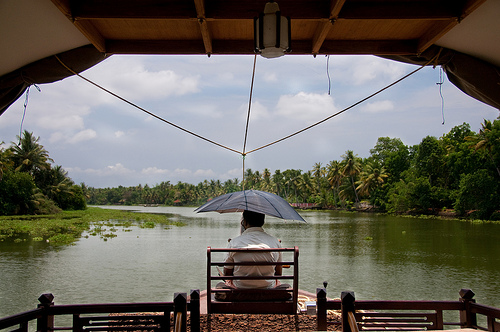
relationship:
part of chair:
[216, 247, 286, 252] [208, 241, 298, 313]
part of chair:
[251, 286, 279, 298] [198, 241, 325, 312]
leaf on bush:
[410, 184, 413, 189] [388, 168, 447, 217]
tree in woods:
[449, 172, 477, 216] [17, 109, 488, 242]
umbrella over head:
[210, 179, 315, 230] [223, 204, 284, 233]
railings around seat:
[42, 293, 197, 322] [208, 253, 298, 312]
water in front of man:
[56, 193, 177, 293] [220, 213, 295, 310]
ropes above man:
[201, 108, 331, 151] [200, 209, 272, 279]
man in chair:
[224, 218, 284, 267] [178, 236, 328, 330]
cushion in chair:
[214, 287, 292, 305] [209, 250, 303, 282]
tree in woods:
[449, 172, 477, 216] [345, 151, 483, 225]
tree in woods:
[399, 169, 466, 207] [367, 157, 453, 208]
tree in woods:
[449, 172, 477, 216] [411, 163, 464, 207]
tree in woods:
[340, 166, 397, 215] [337, 167, 381, 198]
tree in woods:
[336, 166, 360, 201] [348, 157, 442, 196]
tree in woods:
[449, 172, 477, 216] [309, 174, 351, 219]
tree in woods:
[449, 172, 477, 216] [313, 146, 405, 192]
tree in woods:
[449, 172, 477, 216] [263, 168, 315, 200]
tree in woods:
[449, 172, 477, 216] [294, 166, 359, 195]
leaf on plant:
[25, 169, 30, 174] [14, 170, 74, 226]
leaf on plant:
[14, 166, 24, 168] [16, 167, 49, 207]